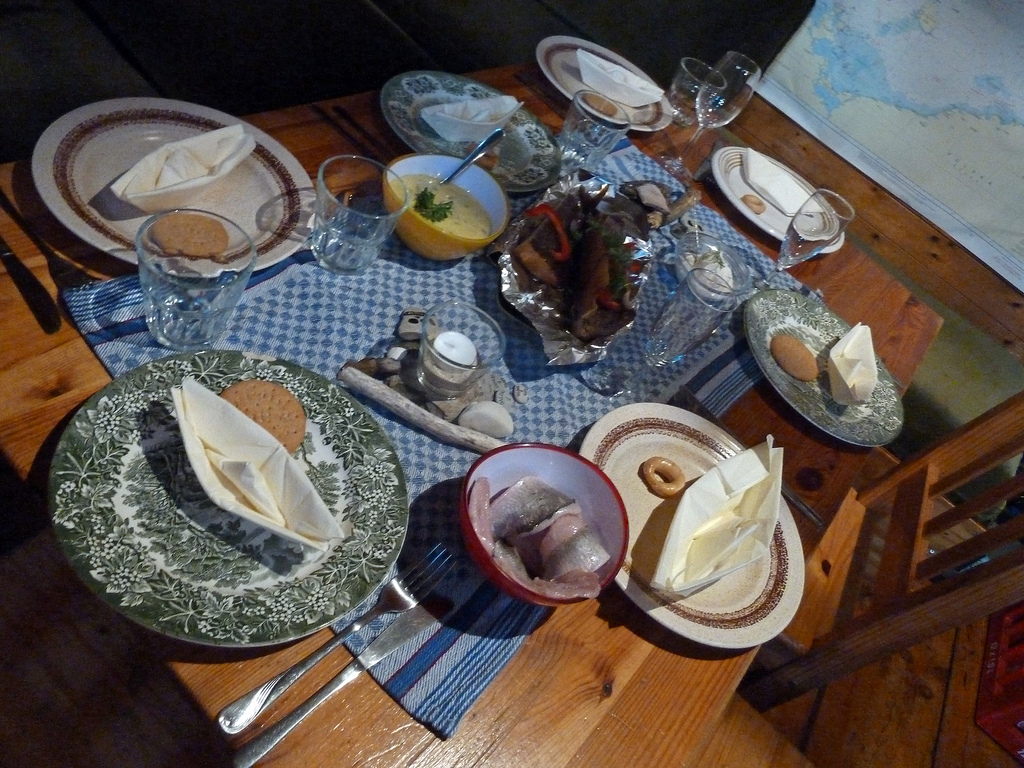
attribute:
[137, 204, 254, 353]
glass — clear 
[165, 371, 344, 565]
napkin —  folded paper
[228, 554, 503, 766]
knife — silver  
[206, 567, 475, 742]
fork — silver  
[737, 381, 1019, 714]
chair — brown 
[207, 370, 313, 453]
cookie — brown 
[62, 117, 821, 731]
table runner — blue 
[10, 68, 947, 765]
table — brown , wooden 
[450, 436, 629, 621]
red bowl — red 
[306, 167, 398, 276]
glass — small 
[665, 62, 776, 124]
glasses — two wine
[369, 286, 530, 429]
glass — clear 